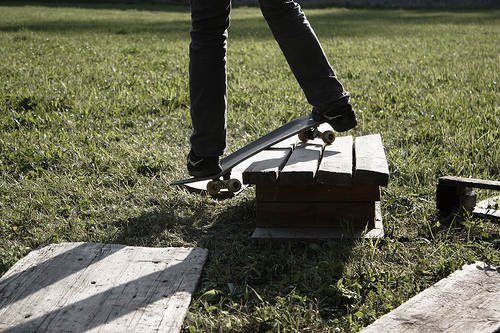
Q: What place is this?
A: It is a yard.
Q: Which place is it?
A: It is a yard.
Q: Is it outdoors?
A: Yes, it is outdoors.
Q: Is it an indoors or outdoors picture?
A: It is outdoors.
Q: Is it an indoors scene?
A: No, it is outdoors.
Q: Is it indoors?
A: No, it is outdoors.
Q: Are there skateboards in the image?
A: Yes, there is a skateboard.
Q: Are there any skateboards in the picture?
A: Yes, there is a skateboard.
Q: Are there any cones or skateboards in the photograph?
A: Yes, there is a skateboard.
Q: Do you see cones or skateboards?
A: Yes, there is a skateboard.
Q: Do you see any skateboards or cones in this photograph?
A: Yes, there is a skateboard.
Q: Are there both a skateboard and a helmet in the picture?
A: No, there is a skateboard but no helmets.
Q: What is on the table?
A: The skateboard is on the table.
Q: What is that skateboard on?
A: The skateboard is on the table.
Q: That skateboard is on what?
A: The skateboard is on the table.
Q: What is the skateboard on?
A: The skateboard is on the table.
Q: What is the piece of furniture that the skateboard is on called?
A: The piece of furniture is a table.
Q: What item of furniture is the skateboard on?
A: The skateboard is on the table.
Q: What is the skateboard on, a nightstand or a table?
A: The skateboard is on a table.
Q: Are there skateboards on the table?
A: Yes, there is a skateboard on the table.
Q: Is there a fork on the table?
A: No, there is a skateboard on the table.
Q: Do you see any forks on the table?
A: No, there is a skateboard on the table.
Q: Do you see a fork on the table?
A: No, there is a skateboard on the table.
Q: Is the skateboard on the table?
A: Yes, the skateboard is on the table.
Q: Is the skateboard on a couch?
A: No, the skateboard is on the table.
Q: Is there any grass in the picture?
A: Yes, there is grass.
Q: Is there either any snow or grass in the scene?
A: Yes, there is grass.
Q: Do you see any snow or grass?
A: Yes, there is grass.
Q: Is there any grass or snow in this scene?
A: Yes, there is grass.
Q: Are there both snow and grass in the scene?
A: No, there is grass but no snow.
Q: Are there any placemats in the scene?
A: No, there are no placemats.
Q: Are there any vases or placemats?
A: No, there are no placemats or vases.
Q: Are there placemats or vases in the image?
A: No, there are no placemats or vases.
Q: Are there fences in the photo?
A: No, there are no fences.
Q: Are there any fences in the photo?
A: No, there are no fences.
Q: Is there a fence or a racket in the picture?
A: No, there are no fences or rackets.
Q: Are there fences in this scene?
A: No, there are no fences.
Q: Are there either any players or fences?
A: No, there are no fences or players.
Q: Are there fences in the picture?
A: No, there are no fences.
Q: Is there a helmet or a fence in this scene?
A: No, there are no fences or helmets.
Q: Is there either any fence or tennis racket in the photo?
A: No, there are no fences or rackets.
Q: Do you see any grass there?
A: Yes, there is grass.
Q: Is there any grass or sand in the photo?
A: Yes, there is grass.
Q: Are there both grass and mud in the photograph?
A: No, there is grass but no mud.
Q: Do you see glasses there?
A: No, there are no glasses.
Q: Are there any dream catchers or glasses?
A: No, there are no glasses or dream catchers.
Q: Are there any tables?
A: Yes, there is a table.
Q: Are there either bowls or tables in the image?
A: Yes, there is a table.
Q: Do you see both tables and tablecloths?
A: No, there is a table but no tablecloths.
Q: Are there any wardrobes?
A: No, there are no wardrobes.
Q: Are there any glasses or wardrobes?
A: No, there are no wardrobes or glasses.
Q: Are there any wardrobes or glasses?
A: No, there are no wardrobes or glasses.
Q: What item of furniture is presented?
A: The piece of furniture is a table.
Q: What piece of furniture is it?
A: The piece of furniture is a table.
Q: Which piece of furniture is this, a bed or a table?
A: That is a table.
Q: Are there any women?
A: No, there are no women.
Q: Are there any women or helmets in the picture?
A: No, there are no women or helmets.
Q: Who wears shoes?
A: The boy wears shoes.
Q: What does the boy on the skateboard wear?
A: The boy wears shoes.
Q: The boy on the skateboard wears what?
A: The boy wears shoes.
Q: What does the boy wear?
A: The boy wears shoes.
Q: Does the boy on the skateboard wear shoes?
A: Yes, the boy wears shoes.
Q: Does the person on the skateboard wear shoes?
A: Yes, the boy wears shoes.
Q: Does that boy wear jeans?
A: No, the boy wears shoes.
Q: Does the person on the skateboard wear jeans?
A: No, the boy wears shoes.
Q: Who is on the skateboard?
A: The boy is on the skateboard.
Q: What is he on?
A: The boy is on the skateboard.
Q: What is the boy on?
A: The boy is on the skateboard.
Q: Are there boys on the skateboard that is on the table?
A: Yes, there is a boy on the skateboard.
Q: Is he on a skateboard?
A: Yes, the boy is on a skateboard.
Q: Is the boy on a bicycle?
A: No, the boy is on a skateboard.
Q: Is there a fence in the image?
A: No, there are no fences.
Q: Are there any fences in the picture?
A: No, there are no fences.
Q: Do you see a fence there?
A: No, there are no fences.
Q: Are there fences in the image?
A: No, there are no fences.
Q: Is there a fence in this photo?
A: No, there are no fences.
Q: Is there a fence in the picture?
A: No, there are no fences.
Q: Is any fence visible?
A: No, there are no fences.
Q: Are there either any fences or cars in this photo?
A: No, there are no fences or cars.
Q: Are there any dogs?
A: No, there are no dogs.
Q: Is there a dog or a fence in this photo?
A: No, there are no dogs or fences.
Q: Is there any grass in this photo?
A: Yes, there is grass.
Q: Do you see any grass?
A: Yes, there is grass.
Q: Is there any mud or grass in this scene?
A: Yes, there is grass.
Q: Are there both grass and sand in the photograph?
A: No, there is grass but no sand.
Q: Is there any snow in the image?
A: No, there is no snow.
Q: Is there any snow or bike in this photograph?
A: No, there are no snow or bikes.